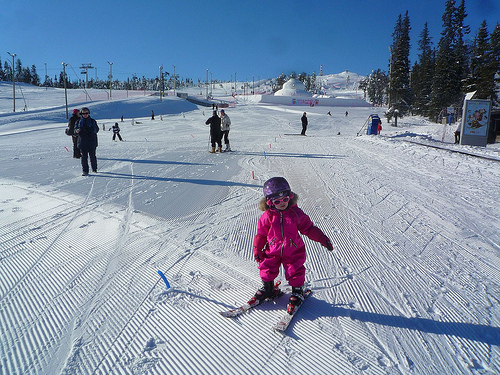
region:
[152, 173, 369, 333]
a little girl in a pink jacket.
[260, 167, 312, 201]
a purple ski helmet.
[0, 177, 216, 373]
a section of tracks in snow.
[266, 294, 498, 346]
a shadow cast on the snow.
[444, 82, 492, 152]
a kiosk in the snow.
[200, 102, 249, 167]
a couple on the snow.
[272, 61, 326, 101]
a large snow pile.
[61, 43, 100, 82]
a ski lift.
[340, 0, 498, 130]
a forest of lush green trees.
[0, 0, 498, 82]
a clear blue sky.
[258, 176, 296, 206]
Child wearing purple helmet.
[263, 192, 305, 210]
Child wearing pink goggles.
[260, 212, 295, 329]
Child wearing pink snow suit.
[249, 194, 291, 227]
Fur on hood on child's coat.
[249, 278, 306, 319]
Child wearing dark boots.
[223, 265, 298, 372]
White skis on kids feet.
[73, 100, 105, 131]
Sunglasses on person's face.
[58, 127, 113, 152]
Dark coat on person walking.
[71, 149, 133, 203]
Person wearing dark pants.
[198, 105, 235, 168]
Person wearing black coat.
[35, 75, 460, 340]
skiers on flat snow trail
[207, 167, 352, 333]
child in bright pink snowsuit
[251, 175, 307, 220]
girl in purple helmet and sunglasses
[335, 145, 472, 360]
ridges crisscrossing the snow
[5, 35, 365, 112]
blue sky against trees and hill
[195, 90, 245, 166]
skiers talking while standing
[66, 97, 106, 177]
person in dark clothes walking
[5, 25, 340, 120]
lamp poles across the trail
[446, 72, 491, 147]
tall trees behind poster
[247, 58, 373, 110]
mound of snow behind low partition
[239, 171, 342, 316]
a toddler stand on the snow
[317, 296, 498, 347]
a shadow cast on the snow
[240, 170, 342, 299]
the toddler wears a pink suit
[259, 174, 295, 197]
a purple helmet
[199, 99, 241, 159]
two people in a snow track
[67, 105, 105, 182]
woman wearing glasses is walking in the snow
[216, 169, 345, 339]
kid stand on snow skis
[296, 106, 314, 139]
a person stand alone on the snow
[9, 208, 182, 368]
marks on the snow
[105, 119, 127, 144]
a kid on the snow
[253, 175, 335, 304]
Girl in pink snowsuit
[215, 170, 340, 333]
Little girl on skis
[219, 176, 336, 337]
Girl on ski slope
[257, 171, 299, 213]
Girl with pink helmet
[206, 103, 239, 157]
People on ski slope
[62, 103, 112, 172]
People on ski slope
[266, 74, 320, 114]
Big mound of snow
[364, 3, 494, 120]
Green trees on slop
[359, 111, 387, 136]
small blue building on slope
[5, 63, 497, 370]
snow covered mountain